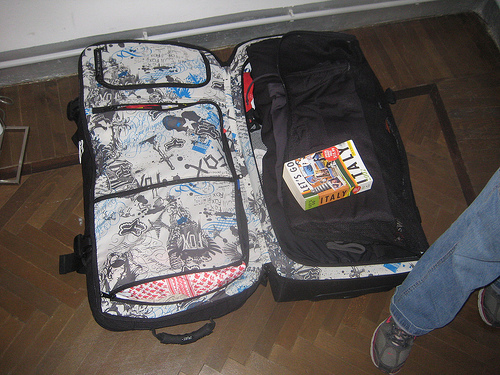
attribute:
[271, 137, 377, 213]
book — italy, paper, thick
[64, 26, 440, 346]
suitcase — black, white, open, patterned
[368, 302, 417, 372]
shoe — black, gray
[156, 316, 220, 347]
handle — black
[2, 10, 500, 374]
floor — brown, wood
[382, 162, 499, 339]
jeans — blue, on right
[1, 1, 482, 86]
wall — white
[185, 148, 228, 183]
logo — fox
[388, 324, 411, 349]
laces — gray